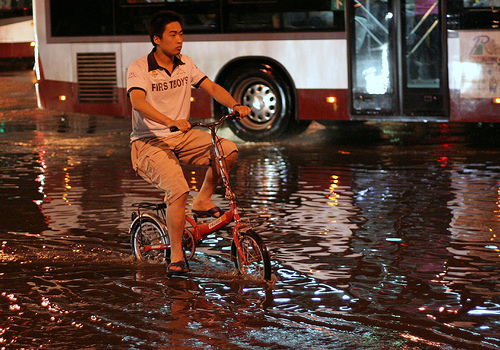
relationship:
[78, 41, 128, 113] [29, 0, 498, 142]
vent on bus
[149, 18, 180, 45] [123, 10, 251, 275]
hair on man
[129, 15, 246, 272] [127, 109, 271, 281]
man riding a bike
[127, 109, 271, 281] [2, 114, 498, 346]
bike on a flooded street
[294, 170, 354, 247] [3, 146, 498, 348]
lights reflecting off water surface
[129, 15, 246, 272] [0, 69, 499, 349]
man biking down flooded street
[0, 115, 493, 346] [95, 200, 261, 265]
water on ground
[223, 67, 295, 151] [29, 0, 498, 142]
tire on bus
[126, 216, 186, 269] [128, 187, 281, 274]
tire on bike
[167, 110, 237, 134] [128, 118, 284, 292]
handlebars are on bike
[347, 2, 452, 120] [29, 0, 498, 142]
doors on bus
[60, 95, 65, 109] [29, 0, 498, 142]
light on bus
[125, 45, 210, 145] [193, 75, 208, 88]
shirt with black trim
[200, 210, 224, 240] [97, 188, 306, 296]
brand name printed on bike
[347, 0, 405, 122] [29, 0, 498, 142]
doors on bus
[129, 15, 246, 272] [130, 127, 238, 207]
man wearing shorts